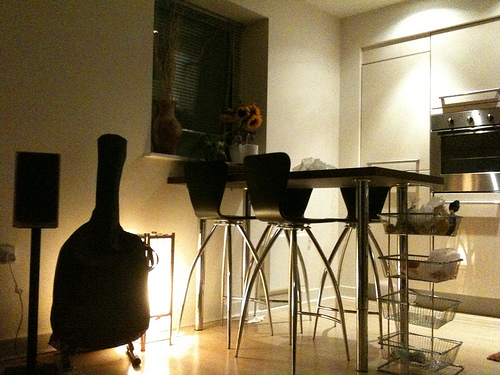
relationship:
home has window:
[0, 3, 494, 373] [156, 1, 243, 151]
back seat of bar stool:
[242, 152, 289, 222] [234, 155, 347, 369]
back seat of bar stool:
[180, 155, 230, 217] [175, 160, 275, 336]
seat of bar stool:
[183, 156, 260, 222] [176, 160, 275, 337]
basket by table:
[381, 247, 462, 280] [166, 162, 450, 185]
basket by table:
[380, 289, 459, 327] [242, 157, 412, 223]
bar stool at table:
[176, 160, 275, 337] [212, 134, 442, 299]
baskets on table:
[378, 198, 466, 372] [193, 165, 445, 369]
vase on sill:
[154, 96, 184, 156] [145, 153, 190, 160]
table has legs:
[203, 119, 457, 353] [195, 189, 415, 369]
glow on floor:
[121, 227, 203, 374] [4, 292, 497, 372]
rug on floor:
[481, 343, 499, 361] [4, 292, 497, 372]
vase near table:
[154, 96, 184, 156] [165, 165, 451, 195]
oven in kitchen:
[422, 82, 499, 202] [6, 4, 498, 369]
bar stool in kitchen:
[176, 160, 275, 337] [6, 4, 498, 369]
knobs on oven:
[443, 112, 498, 125] [429, 88, 499, 193]